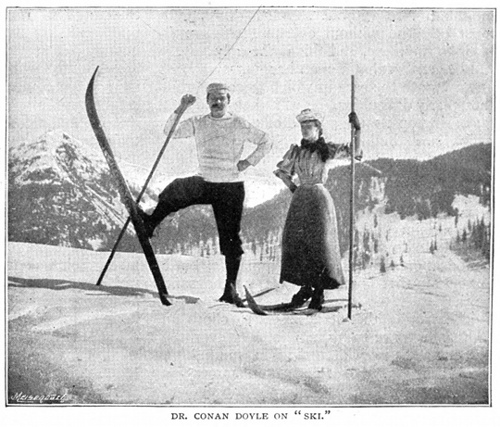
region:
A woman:
[268, 104, 381, 404]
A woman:
[263, 43, 337, 332]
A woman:
[307, 98, 364, 392]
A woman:
[283, 118, 343, 415]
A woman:
[292, 91, 334, 318]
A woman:
[334, 69, 371, 388]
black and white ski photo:
[28, 23, 466, 368]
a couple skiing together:
[73, 54, 385, 323]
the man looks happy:
[82, 49, 262, 322]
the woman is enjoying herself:
[255, 91, 409, 321]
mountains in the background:
[14, 86, 498, 272]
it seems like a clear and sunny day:
[21, 20, 478, 382]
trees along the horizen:
[356, 171, 499, 306]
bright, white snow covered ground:
[36, 256, 458, 394]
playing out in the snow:
[86, 43, 383, 321]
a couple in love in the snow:
[182, 58, 344, 302]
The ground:
[168, 322, 287, 375]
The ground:
[147, 338, 272, 413]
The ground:
[215, 331, 313, 397]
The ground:
[328, 321, 390, 383]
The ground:
[206, 304, 385, 415]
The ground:
[313, 347, 390, 416]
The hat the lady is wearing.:
[293, 105, 324, 121]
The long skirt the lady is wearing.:
[287, 176, 353, 286]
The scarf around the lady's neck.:
[294, 138, 332, 160]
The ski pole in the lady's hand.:
[347, 72, 355, 322]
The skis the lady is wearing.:
[225, 282, 372, 326]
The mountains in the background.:
[14, 119, 496, 276]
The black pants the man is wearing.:
[140, 177, 250, 263]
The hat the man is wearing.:
[201, 74, 233, 96]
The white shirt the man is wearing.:
[164, 112, 261, 186]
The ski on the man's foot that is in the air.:
[69, 64, 201, 331]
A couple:
[156, 106, 329, 284]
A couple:
[156, 111, 361, 411]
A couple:
[231, 83, 368, 348]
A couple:
[211, 93, 447, 268]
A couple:
[233, 185, 373, 408]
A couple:
[191, 159, 321, 379]